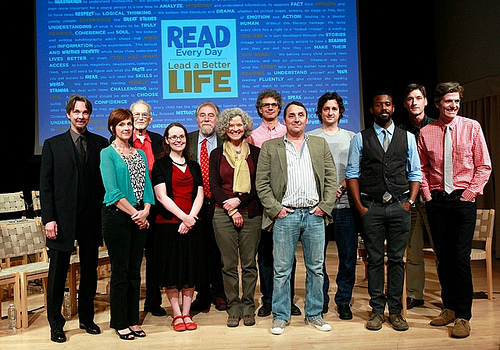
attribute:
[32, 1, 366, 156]
screen — blue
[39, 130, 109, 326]
suit — black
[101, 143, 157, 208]
sweater — blue, turquoise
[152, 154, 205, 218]
shirt — black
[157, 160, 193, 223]
shirt — red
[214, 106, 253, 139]
hair — gray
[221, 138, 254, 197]
scarf — gold, tan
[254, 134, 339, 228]
jacket — gray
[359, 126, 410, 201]
vest — black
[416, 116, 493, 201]
shirt — pink, red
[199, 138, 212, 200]
tie — red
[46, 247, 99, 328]
pants — black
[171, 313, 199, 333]
shoes — red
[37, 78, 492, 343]
people — standing, inside, in a group, smiling, posing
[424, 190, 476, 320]
pants — black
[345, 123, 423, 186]
shirt — blue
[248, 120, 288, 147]
shirt — pink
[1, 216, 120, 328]
chairs — in a row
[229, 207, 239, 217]
bracelet — yellow